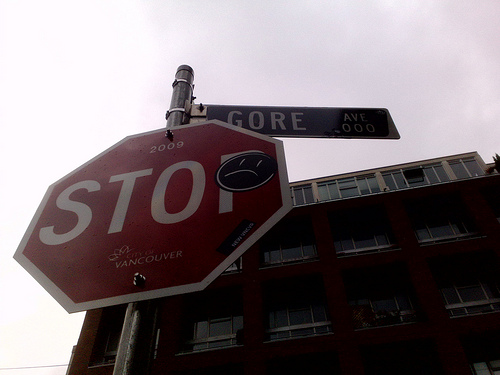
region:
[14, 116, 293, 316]
red stop sign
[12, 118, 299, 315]
red stop sign with black stickers on it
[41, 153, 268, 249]
white print reading STOP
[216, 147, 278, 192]
black sad face sticker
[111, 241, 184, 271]
city text on stop sign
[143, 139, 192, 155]
2009 print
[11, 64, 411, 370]
two signs hanging on pole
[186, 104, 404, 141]
blue street sign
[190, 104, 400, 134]
blue Gore Ave street sign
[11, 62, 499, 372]
brown building behind street sign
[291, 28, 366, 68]
An overcast sky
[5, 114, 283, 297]
A huge red and white stop sign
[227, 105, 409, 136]
Street sign above of stop sign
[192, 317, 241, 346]
Windows of an apartment building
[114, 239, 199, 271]
Logo that reads city of vancouver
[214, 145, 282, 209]
Sad face on stop sign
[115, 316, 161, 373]
Pole that connects to stop sign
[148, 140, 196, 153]
Numbers on stop sign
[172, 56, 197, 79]
Top of the pole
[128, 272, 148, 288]
A screw that screws in the stop sign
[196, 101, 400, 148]
green and white street sign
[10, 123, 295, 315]
red and whtie stop sign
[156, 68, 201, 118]
silver brackets holding sign on to pole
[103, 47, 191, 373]
metal pole holding street signs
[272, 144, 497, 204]
top floor windows in tall building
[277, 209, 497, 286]
second floor windows in tall building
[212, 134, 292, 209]
black face sticker attached to stop sign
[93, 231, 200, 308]
white rpinted sticker attached to stop sign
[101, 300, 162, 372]
ligth reflecting off metal pole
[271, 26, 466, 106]
cloudy gray sky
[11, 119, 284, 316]
The stop sign is defaced.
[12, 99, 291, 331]
The stop sign is in vancouver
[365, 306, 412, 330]
The flowers are on the baclony.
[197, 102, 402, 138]
The sign is blue.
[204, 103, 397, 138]
The street is GORE avenue.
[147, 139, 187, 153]
The sign was installed 2009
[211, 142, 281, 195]
The sticker is a happy face.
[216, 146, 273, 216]
The sticker covers the P.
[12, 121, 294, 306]
The sign has eight sides.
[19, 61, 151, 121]
The sky is over cast.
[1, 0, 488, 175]
The sky is cloudy.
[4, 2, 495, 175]
the sky is grey.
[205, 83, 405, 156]
The sign says Gore.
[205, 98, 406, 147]
the text is white.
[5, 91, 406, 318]
Two signs on pole.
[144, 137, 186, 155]
Sign says number 2009.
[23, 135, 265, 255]
The text is white.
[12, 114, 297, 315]
The stop sign is red.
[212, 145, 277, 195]
A sticker on stop sign.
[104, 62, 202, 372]
The pole is metal.